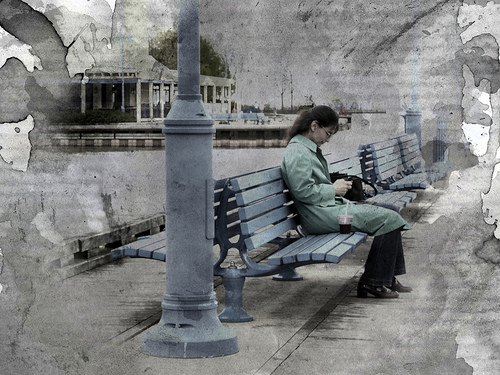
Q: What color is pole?
A: Blue.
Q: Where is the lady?
A: Sitting on bench.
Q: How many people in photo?
A: One.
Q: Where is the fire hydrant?
A: Beside the bench.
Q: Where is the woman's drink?
A: Beside her.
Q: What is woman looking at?
A: Cellphone.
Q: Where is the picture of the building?
A: Background.